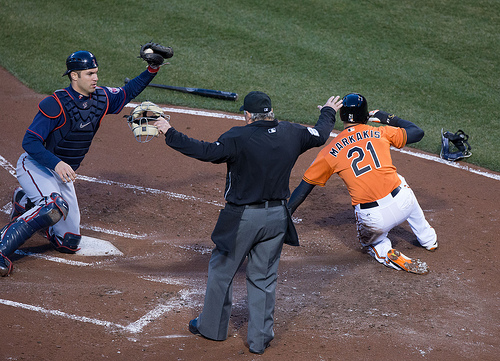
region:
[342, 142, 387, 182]
the number "21" on a jersey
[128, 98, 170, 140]
The Umpire's face helmet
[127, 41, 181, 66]
A baseball players catching glove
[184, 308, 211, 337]
The Umpire's black shoe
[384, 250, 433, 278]
The baseball player's orange cleet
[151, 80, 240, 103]
A black metal baseball bat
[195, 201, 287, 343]
The umpire's dark pants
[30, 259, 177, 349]
The dirt markings of the floor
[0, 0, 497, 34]
The green baseball field's grass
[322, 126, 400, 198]
The baseball player's orange jersey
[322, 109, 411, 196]
man's shirt is orange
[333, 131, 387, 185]
black numbers on shirt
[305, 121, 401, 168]
black letters on shirt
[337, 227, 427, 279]
man's knee on ground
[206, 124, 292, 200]
man's shirt is black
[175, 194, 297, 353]
man's pants are gray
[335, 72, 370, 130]
man wearing black helmet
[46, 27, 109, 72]
man's helmet is black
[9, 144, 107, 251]
man's pants are gray and red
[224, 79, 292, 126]
man's hat is black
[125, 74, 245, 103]
a long black bat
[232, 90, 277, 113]
a black baseball cap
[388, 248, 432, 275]
the shoe of a man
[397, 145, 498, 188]
a long white line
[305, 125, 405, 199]
an orange baseball jersey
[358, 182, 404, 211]
part of a man's black belt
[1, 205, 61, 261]
a man's blue leg pad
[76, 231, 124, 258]
a white base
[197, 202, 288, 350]
a man's gray pants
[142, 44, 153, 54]
a small white baseball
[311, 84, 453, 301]
this player is wearing an orange jersey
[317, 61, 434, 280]
his name is Markakis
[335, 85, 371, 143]
his helmet is black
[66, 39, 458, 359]
markakis is out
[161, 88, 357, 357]
the umpire makes the call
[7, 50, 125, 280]
the catcher has the ball & has his knee on the plate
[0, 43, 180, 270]
this player is wearing a nike vest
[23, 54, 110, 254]
this player is wearing a blue uniform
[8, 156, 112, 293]
his pants are grey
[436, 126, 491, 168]
the catcher's mask is by the baseline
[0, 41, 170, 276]
Catcher making a play at home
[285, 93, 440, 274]
Baseball player sliding in safe at home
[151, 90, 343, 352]
Home plate umpire making safe call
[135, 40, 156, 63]
Baseball in mitt of catcher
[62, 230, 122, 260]
Home plate on a baseball field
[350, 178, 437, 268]
White pants on baseball runner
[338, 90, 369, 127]
Black helmet on baseball runner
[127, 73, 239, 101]
Black bat lying on baseball field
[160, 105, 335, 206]
Black shirt on baseball umpire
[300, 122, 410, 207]
Orange jersey on baseball runner